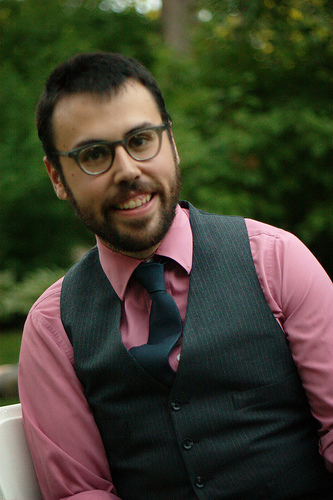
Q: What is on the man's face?
A: Glasses.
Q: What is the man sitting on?
A: A chair.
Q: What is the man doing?
A: Sitting.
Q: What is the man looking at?
A: The camera.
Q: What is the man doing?
A: Smiling.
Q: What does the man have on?
A: A shirt, vest and tie.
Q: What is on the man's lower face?
A: A beard.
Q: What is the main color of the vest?
A: Grey.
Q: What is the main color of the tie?
A: Blue.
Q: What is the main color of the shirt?
A: Pink.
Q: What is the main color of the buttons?
A: Black.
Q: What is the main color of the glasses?
A: Brown.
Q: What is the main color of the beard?
A: Brown.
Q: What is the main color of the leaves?
A: Green.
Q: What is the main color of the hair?
A: Brown.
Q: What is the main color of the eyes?
A: Brown.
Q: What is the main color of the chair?
A: White.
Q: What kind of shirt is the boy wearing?
A: Pink.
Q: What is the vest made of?
A: Material.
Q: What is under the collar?
A: Tie.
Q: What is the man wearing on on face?
A: Glasses.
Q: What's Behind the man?
A: Trees.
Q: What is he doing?
A: Sitting.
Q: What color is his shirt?
A: Pink.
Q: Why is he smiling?
A: For the picture.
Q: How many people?
A: 1.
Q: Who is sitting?
A: The guy.